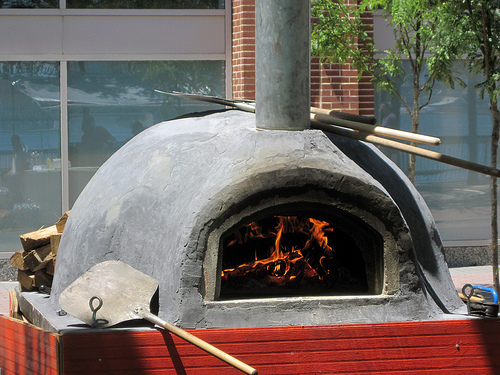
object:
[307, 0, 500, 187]
tree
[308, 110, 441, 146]
stick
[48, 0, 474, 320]
oven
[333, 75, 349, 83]
brick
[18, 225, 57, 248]
log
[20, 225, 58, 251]
firewood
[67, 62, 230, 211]
window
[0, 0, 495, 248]
building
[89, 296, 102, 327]
handle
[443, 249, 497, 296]
concrete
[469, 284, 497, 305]
handle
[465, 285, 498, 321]
iron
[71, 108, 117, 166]
reflection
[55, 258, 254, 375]
spatula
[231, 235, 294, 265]
wood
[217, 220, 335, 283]
fire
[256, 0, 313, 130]
pipe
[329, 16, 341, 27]
leaves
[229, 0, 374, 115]
wall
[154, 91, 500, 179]
poles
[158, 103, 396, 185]
top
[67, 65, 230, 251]
windows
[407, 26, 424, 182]
trunk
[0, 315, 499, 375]
bottom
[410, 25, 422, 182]
branches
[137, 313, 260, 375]
handle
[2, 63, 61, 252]
window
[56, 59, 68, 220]
bar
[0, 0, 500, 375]
background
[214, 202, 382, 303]
hole